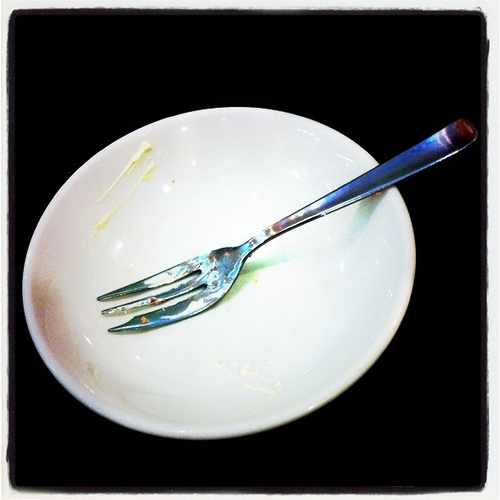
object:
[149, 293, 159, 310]
food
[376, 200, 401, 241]
frosting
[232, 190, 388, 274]
shadow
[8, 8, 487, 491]
table cloth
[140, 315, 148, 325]
crumbs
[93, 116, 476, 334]
fork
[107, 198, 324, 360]
floor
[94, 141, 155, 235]
cream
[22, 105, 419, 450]
plate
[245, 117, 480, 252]
handle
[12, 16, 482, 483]
table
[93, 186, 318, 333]
light reflection